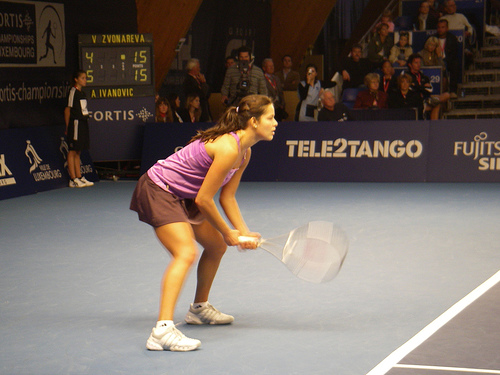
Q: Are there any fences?
A: No, there are no fences.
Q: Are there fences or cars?
A: No, there are no fences or cars.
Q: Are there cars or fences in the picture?
A: No, there are no fences or cars.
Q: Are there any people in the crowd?
A: Yes, there is a person in the crowd.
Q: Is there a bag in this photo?
A: No, there are no bags.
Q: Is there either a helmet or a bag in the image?
A: No, there are no bags or helmets.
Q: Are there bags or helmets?
A: No, there are no bags or helmets.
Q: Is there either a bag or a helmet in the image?
A: No, there are no bags or helmets.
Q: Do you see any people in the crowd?
A: Yes, there is a person in the crowd.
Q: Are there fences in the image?
A: No, there are no fences.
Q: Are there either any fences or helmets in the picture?
A: No, there are no fences or helmets.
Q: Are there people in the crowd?
A: Yes, there is a person in the crowd.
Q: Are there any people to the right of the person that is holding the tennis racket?
A: Yes, there is a person to the right of the girl.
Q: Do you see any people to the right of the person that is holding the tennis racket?
A: Yes, there is a person to the right of the girl.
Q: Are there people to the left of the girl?
A: No, the person is to the right of the girl.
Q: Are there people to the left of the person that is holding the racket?
A: No, the person is to the right of the girl.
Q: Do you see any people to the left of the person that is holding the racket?
A: No, the person is to the right of the girl.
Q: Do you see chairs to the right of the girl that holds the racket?
A: No, there is a person to the right of the girl.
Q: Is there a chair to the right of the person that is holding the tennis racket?
A: No, there is a person to the right of the girl.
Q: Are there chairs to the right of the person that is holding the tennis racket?
A: No, there is a person to the right of the girl.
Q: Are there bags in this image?
A: No, there are no bags.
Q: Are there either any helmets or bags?
A: No, there are no bags or helmets.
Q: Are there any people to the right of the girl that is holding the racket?
A: Yes, there is a person to the right of the girl.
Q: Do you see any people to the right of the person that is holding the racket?
A: Yes, there is a person to the right of the girl.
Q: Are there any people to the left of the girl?
A: No, the person is to the right of the girl.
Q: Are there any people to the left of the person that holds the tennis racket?
A: No, the person is to the right of the girl.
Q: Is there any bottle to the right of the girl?
A: No, there is a person to the right of the girl.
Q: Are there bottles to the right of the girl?
A: No, there is a person to the right of the girl.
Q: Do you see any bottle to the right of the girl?
A: No, there is a person to the right of the girl.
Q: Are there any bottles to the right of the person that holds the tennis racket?
A: No, there is a person to the right of the girl.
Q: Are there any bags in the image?
A: No, there are no bags.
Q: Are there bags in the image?
A: No, there are no bags.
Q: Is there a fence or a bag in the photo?
A: No, there are no bags or fences.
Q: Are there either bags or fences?
A: No, there are no bags or fences.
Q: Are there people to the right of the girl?
A: Yes, there is a person to the right of the girl.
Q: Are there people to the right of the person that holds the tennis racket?
A: Yes, there is a person to the right of the girl.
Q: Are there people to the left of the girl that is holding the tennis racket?
A: No, the person is to the right of the girl.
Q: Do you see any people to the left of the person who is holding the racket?
A: No, the person is to the right of the girl.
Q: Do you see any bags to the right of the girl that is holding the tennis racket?
A: No, there is a person to the right of the girl.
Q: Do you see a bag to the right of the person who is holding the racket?
A: No, there is a person to the right of the girl.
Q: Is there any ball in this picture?
A: No, there are no balls.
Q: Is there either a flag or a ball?
A: No, there are no balls or flags.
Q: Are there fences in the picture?
A: No, there are no fences.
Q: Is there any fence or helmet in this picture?
A: No, there are no fences or helmets.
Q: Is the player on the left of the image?
A: Yes, the player is on the left of the image.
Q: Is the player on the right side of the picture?
A: No, the player is on the left of the image.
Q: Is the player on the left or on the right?
A: The player is on the left of the image.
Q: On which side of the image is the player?
A: The player is on the left of the image.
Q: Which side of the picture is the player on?
A: The player is on the left of the image.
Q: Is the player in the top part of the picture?
A: Yes, the player is in the top of the image.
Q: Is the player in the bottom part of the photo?
A: No, the player is in the top of the image.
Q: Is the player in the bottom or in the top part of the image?
A: The player is in the top of the image.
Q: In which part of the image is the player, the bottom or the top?
A: The player is in the top of the image.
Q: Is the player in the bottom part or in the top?
A: The player is in the top of the image.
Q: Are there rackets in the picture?
A: Yes, there is a racket.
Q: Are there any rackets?
A: Yes, there is a racket.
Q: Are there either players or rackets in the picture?
A: Yes, there is a racket.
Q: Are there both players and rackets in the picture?
A: Yes, there are both a racket and a player.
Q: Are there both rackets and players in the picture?
A: Yes, there are both a racket and a player.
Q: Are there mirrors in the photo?
A: No, there are no mirrors.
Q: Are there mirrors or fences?
A: No, there are no mirrors or fences.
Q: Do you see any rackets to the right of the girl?
A: Yes, there is a racket to the right of the girl.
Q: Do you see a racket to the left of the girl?
A: No, the racket is to the right of the girl.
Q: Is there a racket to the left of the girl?
A: No, the racket is to the right of the girl.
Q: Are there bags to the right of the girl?
A: No, there is a racket to the right of the girl.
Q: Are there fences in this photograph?
A: No, there are no fences.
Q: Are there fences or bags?
A: No, there are no fences or bags.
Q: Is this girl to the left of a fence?
A: No, the girl is to the left of a person.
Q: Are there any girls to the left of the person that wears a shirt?
A: Yes, there is a girl to the left of the person.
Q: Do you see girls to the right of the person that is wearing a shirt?
A: No, the girl is to the left of the person.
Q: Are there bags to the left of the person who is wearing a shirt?
A: No, there is a girl to the left of the person.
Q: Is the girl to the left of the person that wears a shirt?
A: Yes, the girl is to the left of the person.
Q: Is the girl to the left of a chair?
A: No, the girl is to the left of the person.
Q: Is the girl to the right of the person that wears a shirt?
A: No, the girl is to the left of the person.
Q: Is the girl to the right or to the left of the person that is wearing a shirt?
A: The girl is to the left of the person.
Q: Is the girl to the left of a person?
A: Yes, the girl is to the left of a person.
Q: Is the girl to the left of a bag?
A: No, the girl is to the left of a person.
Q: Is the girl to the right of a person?
A: No, the girl is to the left of a person.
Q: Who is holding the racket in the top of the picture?
A: The girl is holding the tennis racket.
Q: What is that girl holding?
A: The girl is holding the tennis racket.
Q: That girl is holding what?
A: The girl is holding the tennis racket.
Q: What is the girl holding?
A: The girl is holding the tennis racket.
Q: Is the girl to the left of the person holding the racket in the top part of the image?
A: Yes, the girl is holding the racket.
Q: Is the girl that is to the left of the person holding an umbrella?
A: No, the girl is holding the racket.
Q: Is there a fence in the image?
A: No, there are no fences.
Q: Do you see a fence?
A: No, there are no fences.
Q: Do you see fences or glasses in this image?
A: No, there are no fences or glasses.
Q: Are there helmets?
A: No, there are no helmets.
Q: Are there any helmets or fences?
A: No, there are no helmets or fences.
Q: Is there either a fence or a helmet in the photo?
A: No, there are no helmets or fences.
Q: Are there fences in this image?
A: No, there are no fences.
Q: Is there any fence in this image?
A: No, there are no fences.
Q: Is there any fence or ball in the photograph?
A: No, there are no fences or balls.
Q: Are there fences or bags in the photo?
A: No, there are no fences or bags.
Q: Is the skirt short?
A: Yes, the skirt is short.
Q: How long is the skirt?
A: The skirt is short.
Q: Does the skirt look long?
A: No, the skirt is short.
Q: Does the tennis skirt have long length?
A: No, the skirt is short.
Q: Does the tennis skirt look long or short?
A: The skirt is short.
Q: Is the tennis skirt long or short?
A: The skirt is short.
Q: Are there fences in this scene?
A: No, there are no fences.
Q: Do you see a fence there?
A: No, there are no fences.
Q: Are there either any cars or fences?
A: No, there are no fences or cars.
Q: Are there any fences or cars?
A: No, there are no fences or cars.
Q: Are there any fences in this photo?
A: No, there are no fences.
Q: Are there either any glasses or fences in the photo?
A: No, there are no fences or glasses.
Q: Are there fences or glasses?
A: No, there are no fences or glasses.